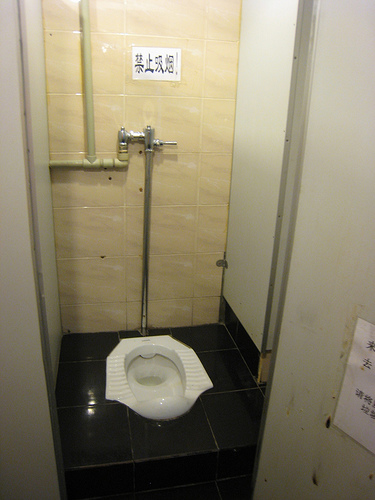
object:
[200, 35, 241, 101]
tile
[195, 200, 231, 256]
tile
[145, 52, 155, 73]
lettering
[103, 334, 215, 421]
toilet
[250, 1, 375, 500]
door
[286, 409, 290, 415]
mark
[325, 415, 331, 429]
mark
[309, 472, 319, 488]
mark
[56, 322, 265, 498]
floor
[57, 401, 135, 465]
tile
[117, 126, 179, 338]
stall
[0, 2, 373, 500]
restroom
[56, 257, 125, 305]
tile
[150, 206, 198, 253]
tile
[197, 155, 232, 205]
tile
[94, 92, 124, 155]
tile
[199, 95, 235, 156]
tile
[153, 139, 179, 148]
handle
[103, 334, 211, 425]
seat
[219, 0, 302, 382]
wall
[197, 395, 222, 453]
line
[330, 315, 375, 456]
sign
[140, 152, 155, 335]
piping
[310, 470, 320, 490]
dirtymarks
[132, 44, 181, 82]
sign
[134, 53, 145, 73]
black letters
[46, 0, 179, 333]
plumbing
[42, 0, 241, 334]
wall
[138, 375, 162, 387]
water